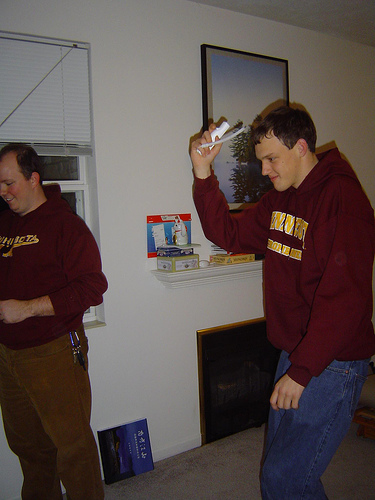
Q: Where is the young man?
A: Behind the older man.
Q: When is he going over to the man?
A: Now.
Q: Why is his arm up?
A: He is holding a remote.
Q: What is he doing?
A: Playing.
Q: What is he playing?
A: A game.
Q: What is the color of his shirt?
A: Wine color.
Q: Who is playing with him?
A: The other man.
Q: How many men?
A: 2.